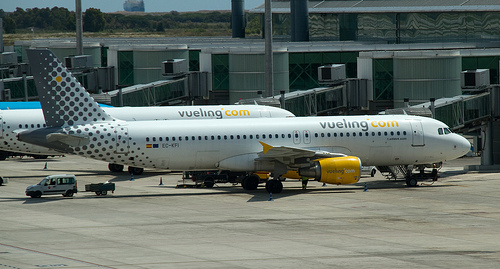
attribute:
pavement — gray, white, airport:
[11, 205, 498, 261]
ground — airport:
[0, 160, 497, 266]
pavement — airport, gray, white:
[171, 191, 391, 253]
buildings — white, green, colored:
[210, 35, 433, 62]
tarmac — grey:
[0, 159, 499, 266]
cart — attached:
[76, 182, 113, 196]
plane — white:
[15, 47, 471, 194]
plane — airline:
[47, 98, 427, 195]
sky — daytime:
[2, 0, 259, 12]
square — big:
[41, 228, 128, 258]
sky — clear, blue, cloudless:
[155, 1, 185, 10]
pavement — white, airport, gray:
[135, 215, 484, 263]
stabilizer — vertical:
[25, 45, 116, 127]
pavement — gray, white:
[1, 153, 484, 266]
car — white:
[20, 170, 74, 197]